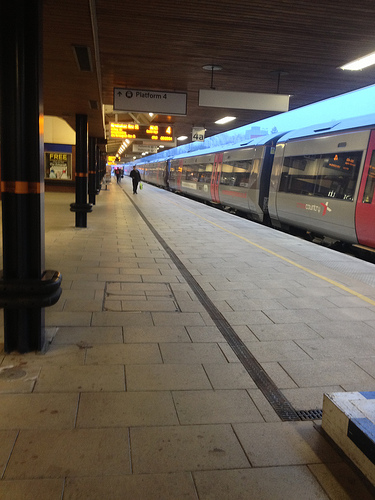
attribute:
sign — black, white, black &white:
[109, 86, 194, 122]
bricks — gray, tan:
[115, 253, 173, 285]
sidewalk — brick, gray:
[4, 147, 373, 499]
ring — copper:
[4, 175, 51, 198]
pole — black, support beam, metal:
[3, 2, 54, 360]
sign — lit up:
[109, 118, 180, 146]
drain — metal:
[290, 395, 326, 427]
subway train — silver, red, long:
[121, 124, 374, 248]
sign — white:
[198, 89, 292, 114]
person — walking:
[126, 164, 147, 202]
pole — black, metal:
[66, 114, 98, 232]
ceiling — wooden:
[44, 4, 374, 148]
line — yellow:
[139, 171, 375, 384]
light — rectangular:
[329, 49, 374, 81]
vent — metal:
[75, 39, 94, 79]